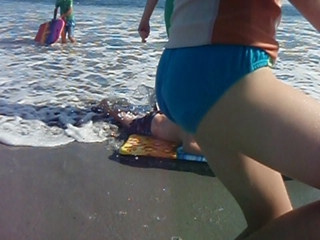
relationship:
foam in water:
[0, 112, 109, 147] [0, 0, 316, 152]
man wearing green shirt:
[54, 0, 82, 44] [54, 0, 74, 19]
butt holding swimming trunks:
[138, 105, 170, 138] [59, 19, 77, 39]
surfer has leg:
[154, 0, 318, 238] [199, 77, 318, 238]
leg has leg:
[199, 77, 318, 238] [193, 134, 294, 239]